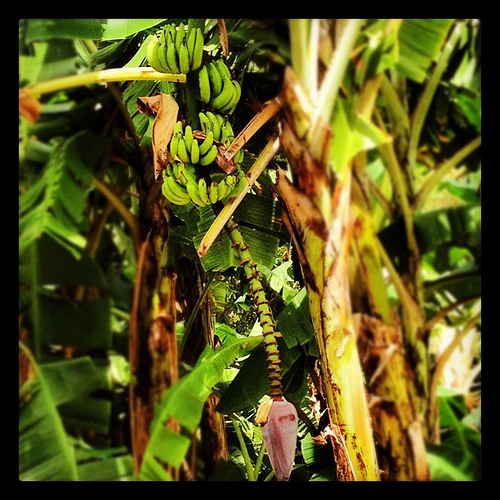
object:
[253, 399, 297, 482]
banana flower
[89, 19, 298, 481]
tree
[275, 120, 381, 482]
tree stalk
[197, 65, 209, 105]
green banana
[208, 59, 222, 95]
green banana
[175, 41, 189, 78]
green banana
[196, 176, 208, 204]
green banana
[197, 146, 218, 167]
green banana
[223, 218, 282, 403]
stem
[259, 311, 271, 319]
bug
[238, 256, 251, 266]
bug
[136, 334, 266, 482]
leaf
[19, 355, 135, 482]
leaf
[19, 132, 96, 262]
leaf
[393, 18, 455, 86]
leaf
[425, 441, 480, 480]
leaf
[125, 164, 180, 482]
tree stalk